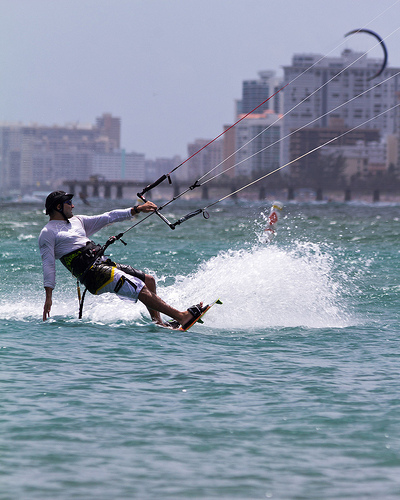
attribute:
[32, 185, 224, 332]
man — surfboarding, wet, leaning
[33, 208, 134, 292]
shirt — white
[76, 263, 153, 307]
shorts — yellow, designed, white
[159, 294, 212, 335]
slippers — black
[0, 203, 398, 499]
water — choppy, calm, white, splashing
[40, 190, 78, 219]
hat — black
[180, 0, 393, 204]
lines — black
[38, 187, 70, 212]
helmet — black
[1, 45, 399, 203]
buildings — distanced, tall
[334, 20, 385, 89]
kite — flying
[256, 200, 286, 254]
buoy — red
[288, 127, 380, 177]
building — brown